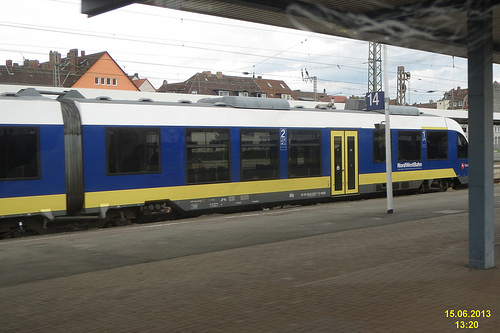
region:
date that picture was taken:
[425, 300, 490, 332]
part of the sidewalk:
[169, 275, 317, 325]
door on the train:
[333, 137, 359, 198]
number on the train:
[275, 123, 290, 155]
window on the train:
[107, 125, 176, 166]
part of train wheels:
[135, 197, 196, 231]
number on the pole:
[365, 90, 390, 122]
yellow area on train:
[110, 191, 183, 203]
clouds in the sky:
[295, 43, 342, 72]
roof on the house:
[209, 78, 237, 90]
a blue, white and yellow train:
[1, 80, 473, 228]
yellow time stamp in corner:
[439, 303, 493, 331]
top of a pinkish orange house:
[53, 48, 155, 95]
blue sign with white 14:
[365, 86, 390, 112]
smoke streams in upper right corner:
[280, 9, 498, 89]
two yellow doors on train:
[328, 124, 369, 211]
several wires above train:
[20, 7, 450, 95]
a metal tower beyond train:
[393, 64, 415, 114]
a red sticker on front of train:
[458, 160, 467, 175]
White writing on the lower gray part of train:
[179, 188, 336, 206]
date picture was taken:
[433, 302, 498, 329]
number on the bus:
[274, 122, 296, 153]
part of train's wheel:
[102, 202, 180, 222]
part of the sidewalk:
[95, 240, 230, 299]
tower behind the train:
[368, 45, 384, 86]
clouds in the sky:
[317, 42, 344, 57]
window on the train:
[115, 136, 156, 169]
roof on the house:
[212, 77, 250, 88]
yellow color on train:
[89, 188, 211, 199]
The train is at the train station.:
[19, 59, 496, 229]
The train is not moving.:
[17, 71, 498, 228]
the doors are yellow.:
[316, 112, 384, 226]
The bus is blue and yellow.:
[19, 93, 483, 253]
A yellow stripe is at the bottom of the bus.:
[49, 148, 489, 246]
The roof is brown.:
[37, 46, 137, 94]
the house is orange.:
[62, 45, 142, 109]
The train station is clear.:
[209, 162, 497, 310]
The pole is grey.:
[447, 28, 497, 209]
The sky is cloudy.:
[277, 45, 359, 99]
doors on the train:
[321, 123, 372, 192]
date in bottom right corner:
[430, 292, 495, 327]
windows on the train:
[168, 132, 318, 207]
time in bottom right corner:
[444, 316, 485, 332]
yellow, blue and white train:
[168, 101, 320, 227]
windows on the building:
[87, 69, 127, 89]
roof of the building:
[66, 53, 87, 69]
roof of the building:
[221, 66, 269, 95]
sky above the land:
[162, 25, 204, 53]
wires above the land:
[151, 31, 194, 65]